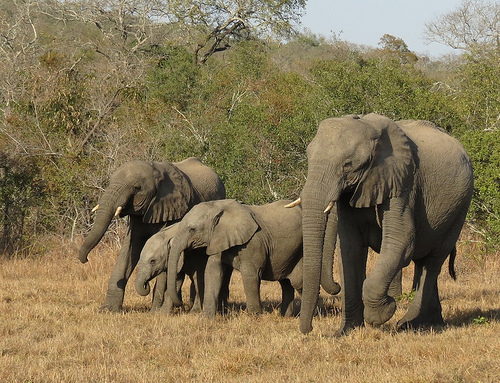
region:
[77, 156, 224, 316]
a grey wrinkly elephant walking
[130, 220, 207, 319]
a grey wrinkly elephant walking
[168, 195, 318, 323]
a grey wrinkly elephant walking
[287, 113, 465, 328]
a grey wrinkly elephant walking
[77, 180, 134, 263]
a long grey wrinkly elephant trunk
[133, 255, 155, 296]
a long grey wrinkly elephant trunk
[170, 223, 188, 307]
a long grey wrinkly elephant trunk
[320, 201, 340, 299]
a long grey wrinkly elephant trunk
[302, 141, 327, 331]
a long grey wrinkly elephant trunk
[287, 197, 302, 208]
a small tusk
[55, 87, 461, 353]
Mother elephant and her babies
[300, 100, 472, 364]
The mother elephant looks in front of her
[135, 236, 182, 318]
Baby elephant curls its trunk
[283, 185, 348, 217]
Elephant has huge tusks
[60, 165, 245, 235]
The elephant has its head raised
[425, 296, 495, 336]
Shadows on the ground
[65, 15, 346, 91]
Large forest in the background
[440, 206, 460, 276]
Elephant has a short tail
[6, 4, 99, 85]
Dead branches near the trees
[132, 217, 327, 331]
The two baby elephants are standing together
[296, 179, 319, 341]
the trunk of an elephant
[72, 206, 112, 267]
the trunk of an elephant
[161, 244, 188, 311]
the trunk of an elephant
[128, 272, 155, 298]
the trunk of an elephant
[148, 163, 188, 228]
an ear of an elephant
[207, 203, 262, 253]
an ear of an elephant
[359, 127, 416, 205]
an ear of an elephant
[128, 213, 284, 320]
two baby elephants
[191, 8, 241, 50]
the branches of a tree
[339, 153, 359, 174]
an eye of an elephant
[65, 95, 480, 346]
four elephants in the savanna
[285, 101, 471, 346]
a big elephant on right side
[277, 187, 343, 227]
two tusks of elephant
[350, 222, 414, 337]
leg of elephant is raised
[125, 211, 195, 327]
a baby elephant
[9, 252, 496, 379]
field is covered with dry grass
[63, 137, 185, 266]
a small elephants with two tusks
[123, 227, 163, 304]
trunk of elephant is fold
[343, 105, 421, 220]
ear of elephant is big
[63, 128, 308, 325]
a baby elephant in middle of two elephants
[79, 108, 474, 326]
Herd of four elephants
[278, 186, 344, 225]
Two white elephant tusks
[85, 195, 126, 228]
Two white elephant tusks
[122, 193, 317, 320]
Two baby elephants walking beside larger ones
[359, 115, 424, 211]
Elephant's large gray ear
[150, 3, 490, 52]
Light blue and gray sky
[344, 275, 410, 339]
Elephant's foot lifted off the ground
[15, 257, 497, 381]
Light brown grass covering the ground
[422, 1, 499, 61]
Tree without leaves in the background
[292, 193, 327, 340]
Long gray elephant trunk